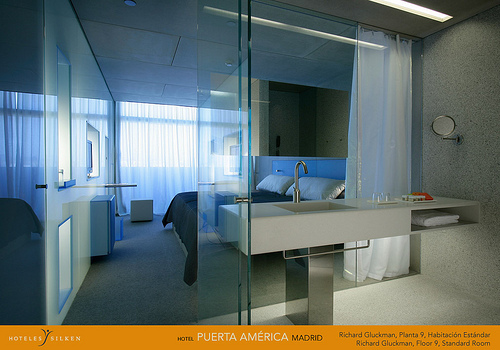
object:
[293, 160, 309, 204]
chrome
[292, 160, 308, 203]
faucet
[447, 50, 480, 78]
wall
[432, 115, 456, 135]
mirror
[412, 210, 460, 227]
white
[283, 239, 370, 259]
bar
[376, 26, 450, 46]
overhead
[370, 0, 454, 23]
light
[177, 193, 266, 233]
nicely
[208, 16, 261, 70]
glass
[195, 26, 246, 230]
opened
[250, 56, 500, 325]
bathroom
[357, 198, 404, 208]
countertop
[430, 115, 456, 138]
small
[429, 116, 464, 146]
on the wall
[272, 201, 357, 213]
white  sink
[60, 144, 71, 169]
clear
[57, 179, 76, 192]
shelf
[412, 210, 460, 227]
towel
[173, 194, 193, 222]
black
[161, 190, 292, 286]
blanket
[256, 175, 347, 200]
white pillows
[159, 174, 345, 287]
bed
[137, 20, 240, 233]
open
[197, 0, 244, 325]
door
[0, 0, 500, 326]
modern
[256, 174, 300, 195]
pillows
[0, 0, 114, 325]
glass wall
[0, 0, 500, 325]
bedroom and bathroo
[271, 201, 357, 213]
sink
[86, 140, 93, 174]
television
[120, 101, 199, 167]
window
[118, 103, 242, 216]
curtain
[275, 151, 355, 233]
area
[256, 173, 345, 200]
two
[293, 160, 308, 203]
long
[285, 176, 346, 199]
pillow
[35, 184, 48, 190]
cup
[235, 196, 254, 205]
silver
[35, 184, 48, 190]
handle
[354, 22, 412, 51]
part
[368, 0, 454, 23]
ceiling light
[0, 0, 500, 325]
room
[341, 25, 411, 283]
curtain